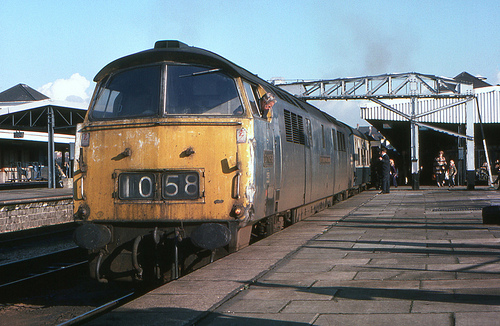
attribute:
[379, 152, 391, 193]
suit — black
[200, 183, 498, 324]
pathway — concrete, brick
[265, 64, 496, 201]
structure — metal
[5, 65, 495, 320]
station — train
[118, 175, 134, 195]
number — white, black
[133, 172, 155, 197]
number — white, black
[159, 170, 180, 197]
number — white, black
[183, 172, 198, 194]
number — white, black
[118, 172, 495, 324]
platform — stone